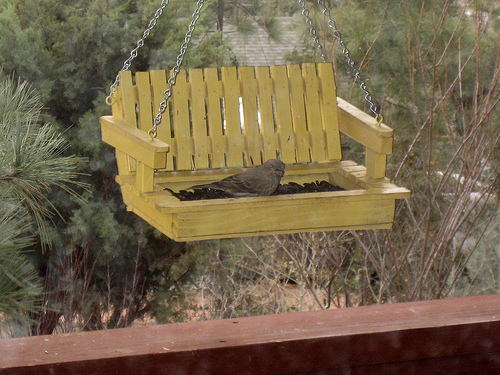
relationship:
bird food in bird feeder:
[177, 171, 343, 196] [99, 56, 411, 247]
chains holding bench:
[121, 15, 210, 125] [84, 47, 414, 214]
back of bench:
[122, 56, 342, 164] [112, 53, 410, 241]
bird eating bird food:
[183, 157, 286, 197] [177, 171, 343, 196]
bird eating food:
[183, 157, 286, 197] [270, 180, 347, 193]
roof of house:
[190, 15, 318, 68] [202, 13, 317, 66]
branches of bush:
[289, 212, 449, 283] [275, 8, 484, 288]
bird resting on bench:
[183, 157, 286, 197] [112, 53, 410, 241]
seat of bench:
[115, 157, 412, 212] [112, 53, 410, 241]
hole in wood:
[231, 318, 240, 324] [1, 292, 498, 373]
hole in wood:
[216, 335, 228, 345] [1, 292, 498, 373]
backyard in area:
[3, 19, 480, 329] [1, 4, 494, 372]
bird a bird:
[184, 159, 286, 197] [184, 159, 286, 197]